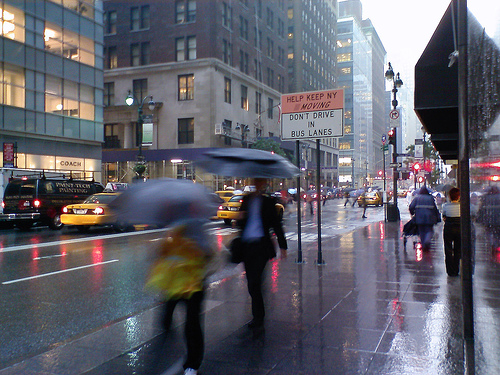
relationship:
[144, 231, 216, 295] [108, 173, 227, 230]
raincoat under umbrella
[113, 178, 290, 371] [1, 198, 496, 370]
pedestrians walking on sidewalk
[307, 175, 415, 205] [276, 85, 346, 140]
traffic steady sign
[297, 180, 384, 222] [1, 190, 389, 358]
pederstrians walking across street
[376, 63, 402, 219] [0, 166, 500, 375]
light on road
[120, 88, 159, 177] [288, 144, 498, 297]
street light on sidewalk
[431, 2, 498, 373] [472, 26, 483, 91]
glass covered in water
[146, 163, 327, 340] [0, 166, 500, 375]
people cross road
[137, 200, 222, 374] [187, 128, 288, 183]
pedestrians holding umbrella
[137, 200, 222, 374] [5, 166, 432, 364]
pedestrians by road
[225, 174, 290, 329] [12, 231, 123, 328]
people by road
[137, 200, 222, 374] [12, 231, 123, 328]
pedestrians by road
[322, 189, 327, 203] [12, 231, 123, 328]
person by road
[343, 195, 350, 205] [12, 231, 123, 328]
person by road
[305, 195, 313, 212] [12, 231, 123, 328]
person by road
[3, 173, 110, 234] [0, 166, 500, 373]
van on road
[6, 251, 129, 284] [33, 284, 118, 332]
lines on road